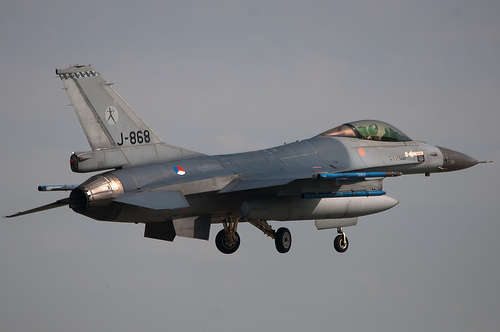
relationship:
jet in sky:
[194, 123, 311, 323] [6, 2, 497, 70]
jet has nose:
[4, 63, 495, 255] [437, 146, 492, 171]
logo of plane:
[167, 159, 192, 178] [41, 63, 475, 261]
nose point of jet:
[463, 149, 495, 175] [4, 63, 495, 255]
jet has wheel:
[4, 63, 495, 255] [332, 232, 349, 252]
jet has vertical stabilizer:
[4, 63, 495, 255] [54, 53, 176, 183]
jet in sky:
[4, 63, 495, 255] [16, 2, 495, 314]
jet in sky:
[4, 63, 495, 255] [24, 16, 476, 326]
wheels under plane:
[213, 220, 353, 268] [41, 63, 475, 261]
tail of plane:
[30, 37, 201, 313] [32, 52, 487, 269]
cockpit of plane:
[324, 119, 414, 142] [3, 62, 493, 252]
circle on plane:
[166, 161, 193, 181] [0, 48, 492, 272]